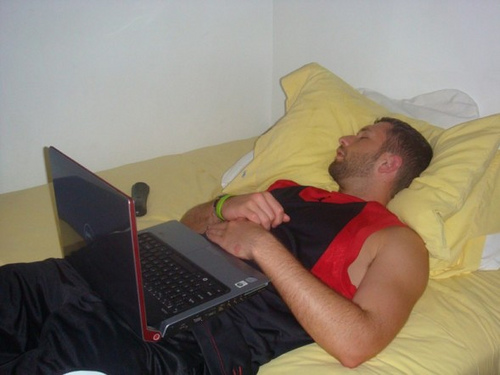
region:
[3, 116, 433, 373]
a man sleeping on a bed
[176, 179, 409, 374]
a red and black shirt on the man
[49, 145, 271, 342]
an open laptop computer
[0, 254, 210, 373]
black pants on the man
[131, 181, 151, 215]
a remote control on the bed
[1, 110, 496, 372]
yellow sheets on the bed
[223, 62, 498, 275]
a yellow pillowcase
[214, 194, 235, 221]
a yellow bracelet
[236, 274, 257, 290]
small stickers on the computer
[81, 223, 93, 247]
Dell logo on the computer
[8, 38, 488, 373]
a bedroom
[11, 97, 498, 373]
a man sleeping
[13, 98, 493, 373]
a man is sleeping on the bed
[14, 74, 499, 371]
the bed has yellow sheets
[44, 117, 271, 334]
a red and grey laptop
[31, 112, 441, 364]
a laptop on the man's stomach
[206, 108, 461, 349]
the man wears a red and black shirt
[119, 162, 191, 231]
a television remote control on the bed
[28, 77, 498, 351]
the man has a beard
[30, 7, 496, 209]
the walls are white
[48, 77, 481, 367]
There is a guy on a bed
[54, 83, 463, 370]
The guy is sleeping on the bed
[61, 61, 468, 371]
The bed linen is yello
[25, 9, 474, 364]
The walls are white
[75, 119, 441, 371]
There is a laptop on the guy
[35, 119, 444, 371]
There is a remote control near the guy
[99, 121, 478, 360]
The man has a beard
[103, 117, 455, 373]
The man is wearing a black and red shirt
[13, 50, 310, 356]
The laptop is open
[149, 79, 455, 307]
The man is laying on a yellow pillowcase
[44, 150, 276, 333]
A Dell laptop.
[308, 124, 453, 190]
A sleeping man.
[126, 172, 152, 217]
A remote control.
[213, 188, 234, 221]
A bracelet.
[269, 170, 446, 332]
A black and red tank top.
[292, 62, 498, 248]
Yellow pillow cases.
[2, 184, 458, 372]
Yellow blankets.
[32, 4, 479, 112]
White walls in the bedroom.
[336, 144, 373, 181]
A beard on the man.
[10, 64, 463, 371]
Twin sized bed.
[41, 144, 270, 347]
Laptop is black, red. and grey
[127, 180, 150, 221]
The TV remote is on the bed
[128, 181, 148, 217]
The remote is black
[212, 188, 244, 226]
The bracelet is lime green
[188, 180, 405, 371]
The shirt is sleeveless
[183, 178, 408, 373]
The shirt is red and black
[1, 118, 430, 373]
The man is sleeping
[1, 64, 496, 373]
The bedding set is yellow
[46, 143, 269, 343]
The laptop is open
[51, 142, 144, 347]
Laptop case is reflective